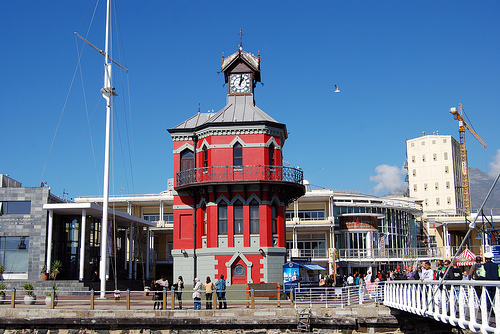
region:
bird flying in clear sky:
[318, 78, 350, 104]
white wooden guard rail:
[445, 282, 495, 329]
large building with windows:
[404, 132, 461, 214]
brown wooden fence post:
[121, 286, 131, 308]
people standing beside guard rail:
[377, 257, 498, 314]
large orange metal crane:
[448, 104, 488, 212]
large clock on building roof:
[224, 71, 256, 95]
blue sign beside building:
[276, 262, 303, 295]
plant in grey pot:
[17, 279, 39, 307]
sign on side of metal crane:
[459, 159, 469, 178]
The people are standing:
[122, 256, 239, 311]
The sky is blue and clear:
[301, 56, 422, 133]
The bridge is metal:
[376, 273, 468, 332]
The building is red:
[159, 90, 304, 297]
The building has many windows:
[1, 192, 56, 320]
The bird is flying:
[315, 62, 371, 128]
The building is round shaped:
[322, 195, 437, 276]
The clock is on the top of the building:
[214, 60, 263, 102]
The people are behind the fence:
[64, 282, 273, 310]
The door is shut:
[228, 256, 258, 292]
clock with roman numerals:
[225, 66, 253, 98]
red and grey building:
[167, 125, 292, 289]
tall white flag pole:
[95, 5, 115, 327]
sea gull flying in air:
[332, 76, 346, 96]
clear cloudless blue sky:
[282, 23, 428, 62]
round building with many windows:
[324, 191, 429, 268]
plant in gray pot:
[18, 280, 38, 306]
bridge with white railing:
[377, 269, 499, 326]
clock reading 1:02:
[224, 67, 249, 94]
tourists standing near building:
[183, 274, 235, 309]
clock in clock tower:
[230, 72, 254, 95]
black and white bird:
[327, 81, 347, 95]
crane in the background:
[449, 104, 495, 216]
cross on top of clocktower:
[236, 23, 248, 50]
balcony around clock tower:
[174, 160, 311, 193]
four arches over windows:
[171, 136, 283, 154]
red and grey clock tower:
[167, 23, 307, 301]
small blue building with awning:
[283, 256, 323, 288]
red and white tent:
[454, 243, 482, 267]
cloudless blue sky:
[370, 8, 483, 73]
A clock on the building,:
[222, 69, 259, 98]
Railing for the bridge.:
[385, 280, 498, 332]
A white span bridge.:
[382, 278, 499, 328]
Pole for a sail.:
[74, 0, 134, 302]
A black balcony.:
[172, 169, 307, 198]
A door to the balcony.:
[175, 152, 197, 186]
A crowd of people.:
[324, 258, 499, 307]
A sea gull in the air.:
[329, 78, 346, 105]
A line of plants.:
[0, 280, 66, 315]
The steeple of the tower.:
[233, 27, 250, 54]